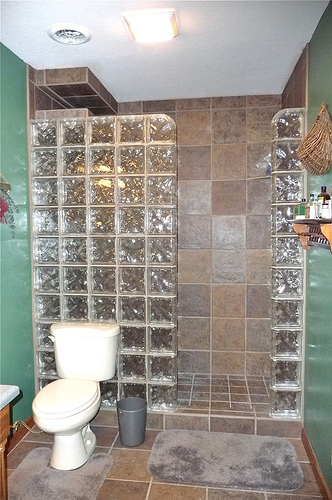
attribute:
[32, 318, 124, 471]
toilet — white, clean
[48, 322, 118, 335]
lid — white, shiny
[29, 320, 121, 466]
toilet — clean, white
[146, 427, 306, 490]
rug — fluffy, gray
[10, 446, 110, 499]
rug — gray, fluffy, toilet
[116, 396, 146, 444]
trashcan — empty, silver, metal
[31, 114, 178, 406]
tile — glass, thick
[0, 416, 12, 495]
cabinet — wood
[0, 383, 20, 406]
counter — white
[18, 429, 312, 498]
rugs — grey, matching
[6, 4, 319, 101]
ceiling — white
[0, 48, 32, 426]
walls — green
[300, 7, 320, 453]
walls — green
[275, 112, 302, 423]
tile — glass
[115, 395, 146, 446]
trash — gray, cylinder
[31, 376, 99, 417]
lid — toilet, white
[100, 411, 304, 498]
floor — tile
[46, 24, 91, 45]
vent — white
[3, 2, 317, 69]
ceiling — white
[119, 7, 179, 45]
light — bright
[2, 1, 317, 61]
ceiling — white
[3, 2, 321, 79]
ceiling — white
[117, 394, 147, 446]
trashcan — gray